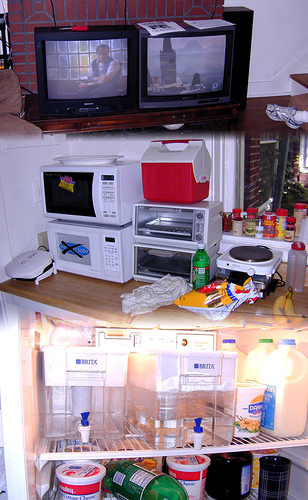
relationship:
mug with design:
[257, 455, 292, 498] [259, 469, 288, 498]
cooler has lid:
[141, 136, 211, 202] [139, 135, 215, 182]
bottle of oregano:
[246, 208, 260, 237] [246, 219, 254, 234]